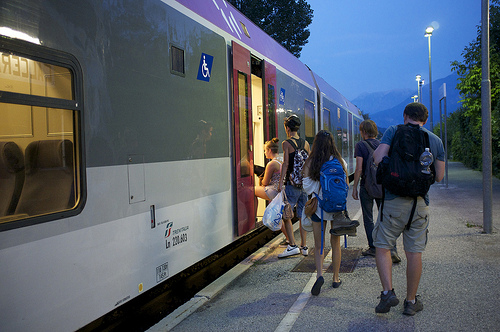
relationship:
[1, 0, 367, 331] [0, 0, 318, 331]
train has car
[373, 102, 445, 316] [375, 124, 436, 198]
man with backpack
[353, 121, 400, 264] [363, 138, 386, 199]
man with backpack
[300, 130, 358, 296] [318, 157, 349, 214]
girl with backpack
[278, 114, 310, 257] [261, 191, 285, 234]
man with bag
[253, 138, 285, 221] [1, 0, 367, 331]
woman boarding train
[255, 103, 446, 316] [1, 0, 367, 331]
passengers boarding train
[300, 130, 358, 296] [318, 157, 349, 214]
girl carrying backpack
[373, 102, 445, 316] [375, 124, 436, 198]
man carrying backpack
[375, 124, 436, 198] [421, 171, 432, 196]
backpack has pocket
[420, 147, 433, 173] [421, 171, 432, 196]
water bottle in pocket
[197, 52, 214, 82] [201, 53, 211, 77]
sign has wheelchair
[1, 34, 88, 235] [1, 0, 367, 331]
window of train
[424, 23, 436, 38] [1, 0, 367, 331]
light over train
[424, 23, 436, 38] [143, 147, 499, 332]
light over boarding area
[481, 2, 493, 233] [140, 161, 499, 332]
pole on sidewalk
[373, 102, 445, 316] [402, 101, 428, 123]
man has hair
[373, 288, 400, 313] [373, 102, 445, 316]
shoe on man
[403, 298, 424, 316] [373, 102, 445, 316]
shoe on man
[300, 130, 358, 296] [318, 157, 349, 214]
girl has backpack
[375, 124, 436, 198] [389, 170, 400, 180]
backpack has red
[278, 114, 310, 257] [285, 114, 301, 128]
man in cap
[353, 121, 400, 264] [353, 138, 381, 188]
man wears shirt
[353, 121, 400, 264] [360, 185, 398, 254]
man wears jeans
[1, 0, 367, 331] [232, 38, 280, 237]
train has doors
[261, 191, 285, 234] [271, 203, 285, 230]
bag has writing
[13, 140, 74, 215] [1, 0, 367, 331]
seat on train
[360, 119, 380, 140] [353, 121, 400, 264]
head of man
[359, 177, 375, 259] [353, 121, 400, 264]
leg of man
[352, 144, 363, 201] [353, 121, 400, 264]
arm of man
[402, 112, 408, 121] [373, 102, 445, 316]
ear of man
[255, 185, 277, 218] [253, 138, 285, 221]
leg of woman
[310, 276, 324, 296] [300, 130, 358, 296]
shoe on girl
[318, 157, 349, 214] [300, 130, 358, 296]
backpack on girl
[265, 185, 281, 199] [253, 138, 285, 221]
shorts on woman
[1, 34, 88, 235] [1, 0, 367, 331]
window on train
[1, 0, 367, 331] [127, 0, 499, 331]
train at station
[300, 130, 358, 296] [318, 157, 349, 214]
girl wearing backpack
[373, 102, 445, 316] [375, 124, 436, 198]
man wearing backpack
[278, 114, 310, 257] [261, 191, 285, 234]
man carrying bag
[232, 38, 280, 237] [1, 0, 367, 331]
doors of train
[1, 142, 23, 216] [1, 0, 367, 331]
seat on train